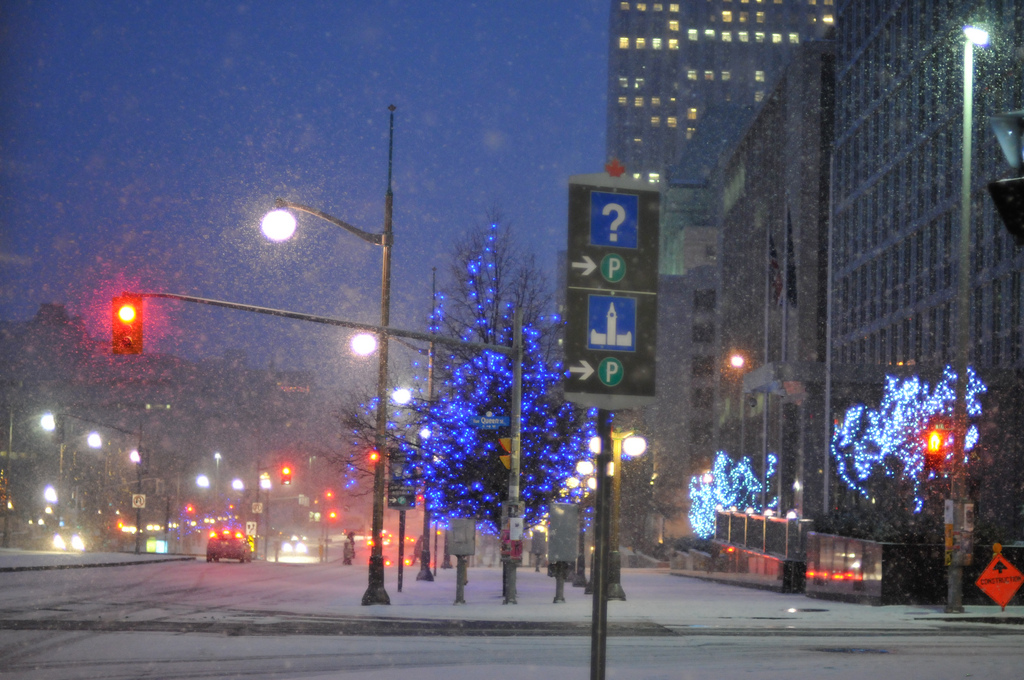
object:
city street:
[2, 0, 1021, 676]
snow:
[0, 0, 514, 680]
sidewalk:
[239, 539, 470, 619]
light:
[113, 289, 144, 342]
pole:
[354, 98, 396, 613]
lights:
[340, 224, 600, 539]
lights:
[436, 416, 655, 593]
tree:
[835, 364, 991, 515]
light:
[922, 429, 950, 457]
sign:
[972, 547, 1021, 611]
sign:
[588, 189, 638, 247]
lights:
[208, 530, 246, 541]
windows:
[621, 0, 808, 47]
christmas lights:
[337, 192, 612, 546]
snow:
[5, 546, 1024, 680]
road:
[5, 546, 1024, 680]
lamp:
[953, 18, 995, 54]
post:
[936, 51, 974, 614]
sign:
[467, 411, 513, 432]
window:
[669, 38, 682, 51]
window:
[662, 0, 682, 30]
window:
[687, 26, 700, 41]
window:
[753, 29, 769, 44]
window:
[719, 28, 733, 41]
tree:
[329, 198, 596, 559]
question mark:
[591, 189, 637, 247]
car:
[204, 532, 254, 565]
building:
[606, 0, 836, 193]